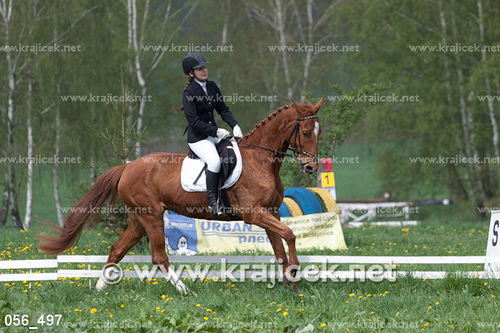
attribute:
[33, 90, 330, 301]
horse — brown, running, large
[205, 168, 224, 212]
riding boot — black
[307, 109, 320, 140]
spot — white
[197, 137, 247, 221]
boots — riding boots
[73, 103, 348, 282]
horse — white, brown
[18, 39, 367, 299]
horse — brown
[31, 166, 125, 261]
tail — long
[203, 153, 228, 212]
boot — tall, black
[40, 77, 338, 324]
horse — brown, white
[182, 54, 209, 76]
helmet — black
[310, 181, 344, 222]
tire — yellow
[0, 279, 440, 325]
flowers — yellow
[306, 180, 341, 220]
tire — yellow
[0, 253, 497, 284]
fence — white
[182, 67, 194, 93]
hair — braided